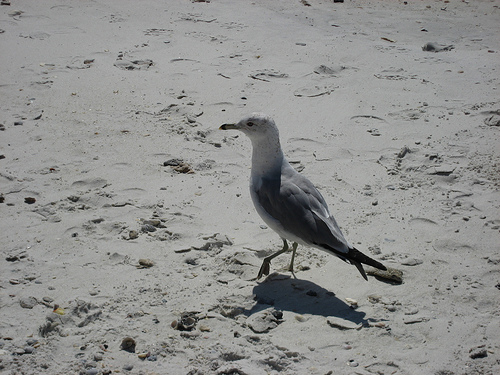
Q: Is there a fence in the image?
A: No, there are no fences.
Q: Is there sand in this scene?
A: Yes, there is sand.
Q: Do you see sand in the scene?
A: Yes, there is sand.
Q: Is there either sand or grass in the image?
A: Yes, there is sand.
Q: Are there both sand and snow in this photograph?
A: No, there is sand but no snow.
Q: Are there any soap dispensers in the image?
A: No, there are no soap dispensers.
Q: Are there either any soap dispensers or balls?
A: No, there are no soap dispensers or balls.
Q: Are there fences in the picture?
A: No, there are no fences.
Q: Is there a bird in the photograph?
A: Yes, there is a bird.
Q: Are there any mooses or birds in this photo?
A: Yes, there is a bird.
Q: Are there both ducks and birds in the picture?
A: No, there is a bird but no ducks.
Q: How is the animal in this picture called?
A: The animal is a bird.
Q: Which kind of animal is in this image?
A: The animal is a bird.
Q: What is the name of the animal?
A: The animal is a bird.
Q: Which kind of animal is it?
A: The animal is a bird.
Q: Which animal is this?
A: This is a bird.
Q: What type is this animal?
A: This is a bird.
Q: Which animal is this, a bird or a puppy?
A: This is a bird.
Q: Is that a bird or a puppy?
A: That is a bird.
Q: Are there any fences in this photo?
A: No, there are no fences.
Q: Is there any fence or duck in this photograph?
A: No, there are no fences or ducks.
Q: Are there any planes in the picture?
A: No, there are no planes.